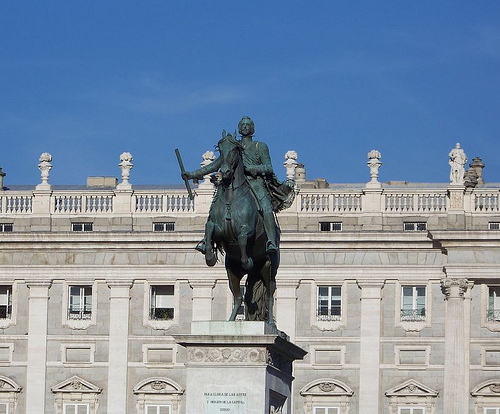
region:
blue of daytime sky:
[3, 2, 498, 182]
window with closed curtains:
[402, 283, 426, 319]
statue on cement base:
[174, 113, 294, 413]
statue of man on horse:
[175, 118, 298, 320]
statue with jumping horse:
[175, 115, 293, 323]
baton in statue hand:
[174, 143, 218, 203]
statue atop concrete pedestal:
[162, 108, 307, 322]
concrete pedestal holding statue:
[170, 300, 314, 412]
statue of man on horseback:
[167, 107, 302, 327]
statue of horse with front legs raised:
[194, 123, 284, 320]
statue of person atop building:
[442, 138, 468, 190]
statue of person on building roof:
[444, 140, 468, 190]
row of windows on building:
[2, 270, 497, 335]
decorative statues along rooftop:
[5, 139, 498, 198]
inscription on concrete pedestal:
[197, 385, 252, 412]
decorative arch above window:
[300, 375, 356, 399]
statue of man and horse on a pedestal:
[172, 115, 306, 409]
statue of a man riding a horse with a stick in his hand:
[174, 115, 297, 320]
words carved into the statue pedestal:
[173, 320, 305, 412]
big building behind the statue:
[0, 143, 499, 413]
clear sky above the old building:
[1, 1, 498, 185]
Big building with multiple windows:
[1, 141, 498, 409]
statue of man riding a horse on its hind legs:
[173, 115, 295, 318]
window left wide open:
[148, 283, 173, 318]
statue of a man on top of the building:
[446, 142, 466, 184]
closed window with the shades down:
[400, 282, 429, 318]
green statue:
[158, 103, 292, 320]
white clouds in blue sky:
[400, 36, 440, 56]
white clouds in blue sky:
[40, 25, 87, 56]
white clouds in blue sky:
[228, 82, 286, 103]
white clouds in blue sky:
[337, 18, 409, 95]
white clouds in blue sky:
[111, 55, 175, 99]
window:
[304, 276, 344, 328]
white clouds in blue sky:
[108, 39, 172, 91]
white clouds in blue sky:
[27, 85, 115, 130]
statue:
[171, 108, 294, 328]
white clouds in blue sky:
[368, 42, 400, 75]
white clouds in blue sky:
[418, 31, 461, 63]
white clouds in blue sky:
[64, 36, 108, 72]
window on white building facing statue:
[0, 285, 7, 318]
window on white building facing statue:
[7, 286, 13, 317]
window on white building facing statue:
[69, 284, 81, 316]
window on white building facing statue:
[81, 285, 91, 313]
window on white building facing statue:
[149, 284, 173, 319]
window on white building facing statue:
[232, 286, 244, 317]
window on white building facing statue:
[316, 285, 329, 315]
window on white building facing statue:
[330, 284, 342, 315]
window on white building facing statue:
[402, 286, 412, 317]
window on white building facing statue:
[415, 285, 425, 315]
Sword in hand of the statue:
[149, 124, 227, 221]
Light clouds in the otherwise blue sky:
[33, 31, 369, 144]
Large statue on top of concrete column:
[171, 118, 326, 305]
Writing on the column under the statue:
[160, 321, 312, 403]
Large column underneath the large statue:
[163, 312, 341, 404]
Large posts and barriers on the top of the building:
[28, 144, 400, 214]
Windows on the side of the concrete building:
[303, 252, 451, 332]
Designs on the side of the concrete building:
[26, 260, 131, 405]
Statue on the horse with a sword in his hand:
[177, 130, 304, 312]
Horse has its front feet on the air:
[179, 137, 309, 329]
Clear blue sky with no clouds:
[1, 0, 498, 184]